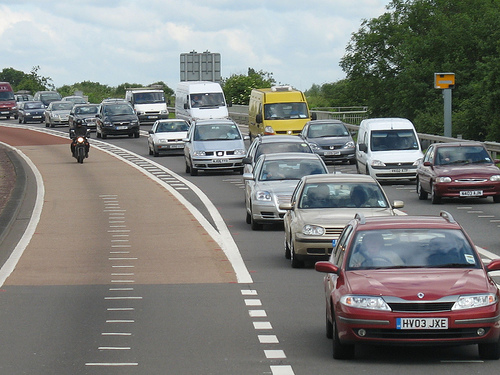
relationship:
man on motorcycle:
[69, 118, 95, 138] [68, 118, 93, 165]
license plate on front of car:
[393, 315, 456, 333] [316, 219, 498, 359]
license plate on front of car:
[456, 188, 485, 198] [421, 140, 495, 204]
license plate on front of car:
[168, 144, 185, 151] [311, 209, 498, 360]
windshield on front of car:
[343, 231, 482, 270] [316, 219, 498, 359]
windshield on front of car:
[291, 185, 388, 210] [286, 184, 391, 264]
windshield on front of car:
[343, 227, 482, 270] [248, 157, 333, 225]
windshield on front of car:
[343, 227, 482, 270] [311, 209, 498, 360]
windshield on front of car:
[343, 227, 482, 270] [421, 140, 495, 204]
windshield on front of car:
[343, 227, 482, 270] [302, 122, 356, 163]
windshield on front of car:
[343, 227, 482, 270] [70, 104, 99, 133]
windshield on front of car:
[343, 227, 482, 270] [46, 101, 66, 125]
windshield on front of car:
[343, 227, 482, 270] [19, 104, 48, 123]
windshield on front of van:
[369, 128, 419, 150] [357, 116, 421, 185]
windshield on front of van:
[267, 99, 310, 120] [248, 89, 311, 138]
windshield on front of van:
[259, 99, 312, 120] [174, 83, 229, 120]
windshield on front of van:
[132, 89, 167, 105] [125, 91, 167, 122]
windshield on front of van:
[100, 105, 136, 120] [93, 101, 142, 137]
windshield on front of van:
[0, 92, 14, 100] [0, 76, 14, 123]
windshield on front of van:
[197, 124, 243, 142] [186, 120, 245, 177]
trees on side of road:
[375, 0, 497, 149] [30, 74, 493, 374]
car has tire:
[421, 140, 495, 204] [427, 178, 442, 202]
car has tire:
[316, 219, 498, 359] [427, 178, 442, 202]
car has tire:
[316, 219, 498, 359] [325, 318, 351, 357]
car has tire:
[311, 209, 498, 360] [153, 146, 164, 156]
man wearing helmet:
[68, 118, 93, 165] [74, 118, 86, 130]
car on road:
[311, 209, 498, 360] [30, 74, 493, 374]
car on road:
[421, 140, 495, 204] [30, 74, 493, 374]